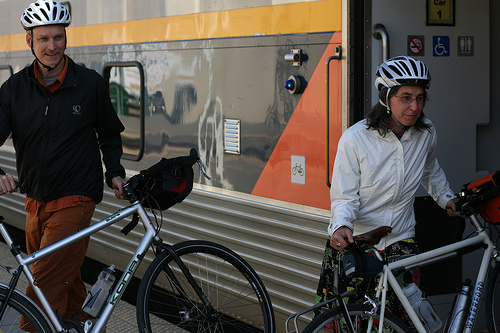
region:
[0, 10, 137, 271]
a man holding a bike up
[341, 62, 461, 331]
a woman holding a bike up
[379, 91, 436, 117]
a woman wearing glasses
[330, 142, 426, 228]
a woman wearing a white jacket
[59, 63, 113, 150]
a man wearing a black jacket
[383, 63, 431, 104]
a woman wearing a black and white helmet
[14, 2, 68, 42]
a man wearing a black and white helmet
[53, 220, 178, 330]
a silver bike with a plastic water bottle attaced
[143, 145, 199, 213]
a black and red bag on a a bike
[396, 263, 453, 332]
a plastic water bottle on a bike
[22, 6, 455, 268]
these people are cyclists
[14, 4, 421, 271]
these are two people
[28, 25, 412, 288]
this is a man and a woman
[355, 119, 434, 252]
this is the woman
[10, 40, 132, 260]
this is the man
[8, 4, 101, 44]
the man is wearing a helmet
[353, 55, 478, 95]
the helmet is silver and black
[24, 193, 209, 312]
this is a bike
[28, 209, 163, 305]
the bike is silver and green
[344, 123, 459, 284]
the woman's jacket is white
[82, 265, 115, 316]
this is a water bottle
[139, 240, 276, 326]
this is a bicycle wheel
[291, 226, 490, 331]
this is a bicycle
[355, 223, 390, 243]
this is a bicycle seat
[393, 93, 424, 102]
these are the spectacles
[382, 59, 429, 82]
this is a cycling cap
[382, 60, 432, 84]
the cycling cap is black and white n colour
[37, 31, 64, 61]
this is a face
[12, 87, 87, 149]
this is a chest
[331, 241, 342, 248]
this is a ring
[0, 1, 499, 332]
Silver bus with yellow stripe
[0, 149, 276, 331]
Silver bike man is holding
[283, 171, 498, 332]
White bike woman is holding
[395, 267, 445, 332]
Water bottle attached to bike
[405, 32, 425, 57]
No smoking sign on bus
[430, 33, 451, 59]
Blue and white handicap sign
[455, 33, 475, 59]
Unisex bathroom sign on bus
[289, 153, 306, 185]
Bike sign on bus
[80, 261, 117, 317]
Water bottle attached to bike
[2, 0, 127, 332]
Man wearing a helmet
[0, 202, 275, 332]
white and black bike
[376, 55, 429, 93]
white helmet on head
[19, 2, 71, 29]
white and black helmet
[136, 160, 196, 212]
black bag on bike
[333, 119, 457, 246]
white wind breaker jacket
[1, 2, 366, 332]
grey and orange bus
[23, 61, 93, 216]
orange cotton polo shirt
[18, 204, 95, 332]
orange cotton cargo pants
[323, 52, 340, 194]
metal bar on bus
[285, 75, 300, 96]
blue light on bus